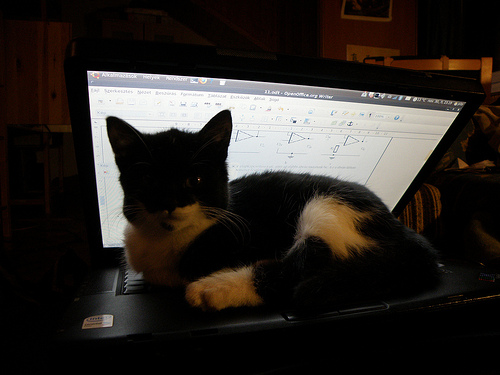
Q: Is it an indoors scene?
A: Yes, it is indoors.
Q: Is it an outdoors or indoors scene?
A: It is indoors.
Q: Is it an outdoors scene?
A: No, it is indoors.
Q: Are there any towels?
A: No, there are no towels.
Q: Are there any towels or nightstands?
A: No, there are no towels or nightstands.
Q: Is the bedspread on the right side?
A: Yes, the bedspread is on the right of the image.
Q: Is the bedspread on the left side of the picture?
A: No, the bedspread is on the right of the image.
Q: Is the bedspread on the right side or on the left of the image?
A: The bedspread is on the right of the image.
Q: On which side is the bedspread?
A: The bedspread is on the right of the image.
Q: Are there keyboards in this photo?
A: Yes, there is a keyboard.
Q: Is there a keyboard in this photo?
A: Yes, there is a keyboard.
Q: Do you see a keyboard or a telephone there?
A: Yes, there is a keyboard.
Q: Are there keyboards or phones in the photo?
A: Yes, there is a keyboard.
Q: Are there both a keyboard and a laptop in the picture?
A: Yes, there are both a keyboard and a laptop.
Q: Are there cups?
A: No, there are no cups.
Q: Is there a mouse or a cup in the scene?
A: No, there are no cups or computer mice.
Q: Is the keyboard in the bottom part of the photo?
A: Yes, the keyboard is in the bottom of the image.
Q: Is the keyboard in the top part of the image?
A: No, the keyboard is in the bottom of the image.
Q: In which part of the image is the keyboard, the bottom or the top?
A: The keyboard is in the bottom of the image.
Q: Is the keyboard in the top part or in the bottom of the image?
A: The keyboard is in the bottom of the image.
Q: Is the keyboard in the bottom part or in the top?
A: The keyboard is in the bottom of the image.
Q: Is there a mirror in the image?
A: No, there are no mirrors.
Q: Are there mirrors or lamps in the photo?
A: No, there are no mirrors or lamps.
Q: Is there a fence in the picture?
A: No, there are no fences.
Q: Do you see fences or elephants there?
A: No, there are no fences or elephants.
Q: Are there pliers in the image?
A: No, there are no pliers.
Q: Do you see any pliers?
A: No, there are no pliers.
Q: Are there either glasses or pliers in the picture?
A: No, there are no pliers or glasses.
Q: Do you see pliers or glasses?
A: No, there are no pliers or glasses.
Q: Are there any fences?
A: No, there are no fences.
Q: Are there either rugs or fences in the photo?
A: No, there are no fences or rugs.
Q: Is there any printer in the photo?
A: No, there are no printers.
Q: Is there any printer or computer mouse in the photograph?
A: No, there are no printers or computer mice.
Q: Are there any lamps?
A: No, there are no lamps.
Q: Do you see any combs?
A: No, there are no combs.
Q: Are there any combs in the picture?
A: No, there are no combs.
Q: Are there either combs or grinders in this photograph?
A: No, there are no combs or grinders.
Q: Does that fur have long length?
A: Yes, the fur is long.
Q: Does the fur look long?
A: Yes, the fur is long.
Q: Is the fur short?
A: No, the fur is long.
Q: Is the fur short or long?
A: The fur is long.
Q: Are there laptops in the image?
A: Yes, there is a laptop.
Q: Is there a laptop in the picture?
A: Yes, there is a laptop.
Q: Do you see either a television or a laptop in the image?
A: Yes, there is a laptop.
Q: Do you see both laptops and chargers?
A: No, there is a laptop but no chargers.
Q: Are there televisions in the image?
A: No, there are no televisions.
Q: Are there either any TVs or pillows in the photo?
A: No, there are no TVs or pillows.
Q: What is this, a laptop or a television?
A: This is a laptop.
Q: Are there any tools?
A: No, there are no tools.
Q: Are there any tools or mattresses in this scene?
A: No, there are no tools or mattresses.